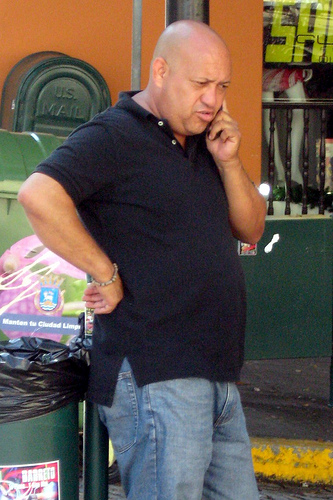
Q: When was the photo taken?
A: Daytime.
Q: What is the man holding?
A: A phone.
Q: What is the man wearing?
A: Jeans.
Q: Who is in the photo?
A: A man.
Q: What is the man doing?
A: Using the phone.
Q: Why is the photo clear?
A: Its during the day.